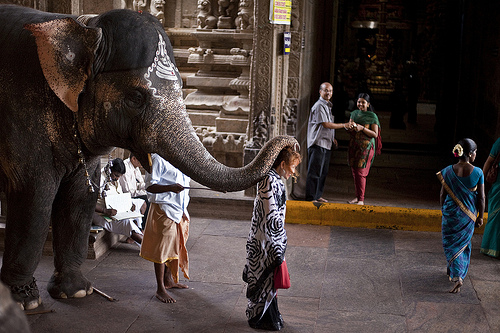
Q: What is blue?
A: Woman's outfit.